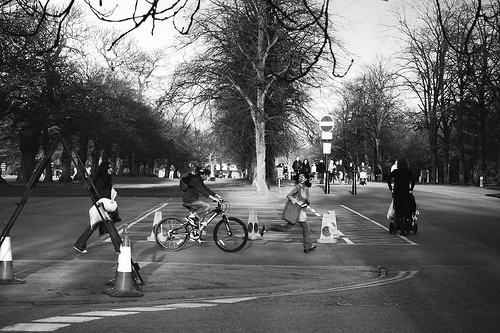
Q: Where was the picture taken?
A: Crosswalk.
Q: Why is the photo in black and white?
A: Art.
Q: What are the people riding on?
A: Bikes.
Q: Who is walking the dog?
A: Nobody.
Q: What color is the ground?
A: Grey.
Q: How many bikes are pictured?
A: 3.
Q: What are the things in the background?
A: Trees.